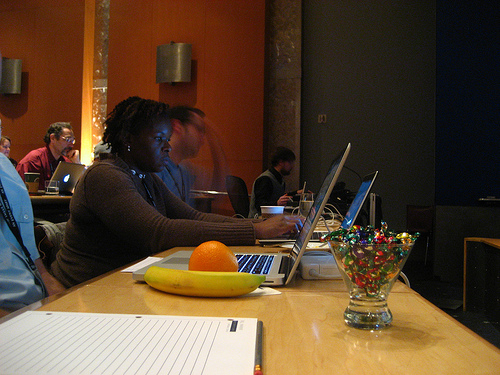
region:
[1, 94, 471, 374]
people sitting at a table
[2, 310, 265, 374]
lined writing paper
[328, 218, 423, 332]
a glass dish containing wrapped candies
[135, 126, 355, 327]
a laptop on the table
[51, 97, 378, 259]
woman with her hands on a laptop computer's keyboard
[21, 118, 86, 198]
man leaning his hand on his chin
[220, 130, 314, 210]
man sitting in a chair close to the wall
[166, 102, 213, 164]
man wearing dark rimmed glasses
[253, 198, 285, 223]
the top of a cup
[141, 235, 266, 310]
a banana sitting beside an orange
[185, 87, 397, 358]
computers on a table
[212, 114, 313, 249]
computers on a table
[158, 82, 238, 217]
a man rubbing his head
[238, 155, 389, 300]
a few open laptops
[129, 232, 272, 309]
a pair of fruits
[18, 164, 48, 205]
a to go coffee cup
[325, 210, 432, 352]
a glass full of candy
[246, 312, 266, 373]
a grey pencil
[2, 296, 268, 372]
a white legal pad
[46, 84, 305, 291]
a woman with curly hair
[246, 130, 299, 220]
a man wearing a vest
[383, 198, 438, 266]
a dark brown chair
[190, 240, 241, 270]
a big orange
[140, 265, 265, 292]
a long yellow banana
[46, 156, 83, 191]
a laptop computer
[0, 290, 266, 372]
a pencil and pad of notebook paper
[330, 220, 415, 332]
a tall glass dish of candy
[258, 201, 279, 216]
a plastic cup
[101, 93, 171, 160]
a black natural hairstyle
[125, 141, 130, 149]
small female earrings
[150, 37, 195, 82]
a gray wall sconce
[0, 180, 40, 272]
a dark lanyard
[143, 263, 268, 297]
banana next to computer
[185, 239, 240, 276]
orange next to computer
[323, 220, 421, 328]
vase full of candy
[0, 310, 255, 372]
blank pad of paper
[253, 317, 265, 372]
pencil above paper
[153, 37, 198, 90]
silver light fixture on wall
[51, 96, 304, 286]
woman in brown shirt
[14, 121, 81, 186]
man wearing red shirt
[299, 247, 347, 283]
white charger behind laptop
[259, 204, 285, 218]
white and brown coffee cup